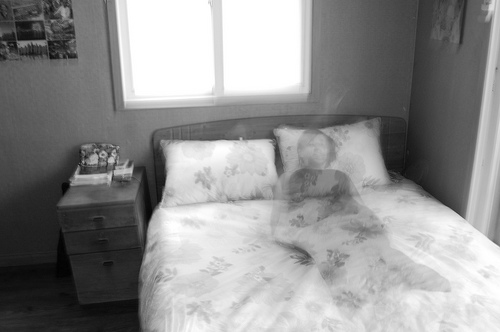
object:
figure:
[266, 129, 452, 316]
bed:
[131, 119, 499, 332]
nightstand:
[54, 165, 146, 308]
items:
[113, 159, 132, 181]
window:
[105, 1, 320, 103]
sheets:
[131, 174, 500, 331]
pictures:
[0, 0, 76, 63]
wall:
[4, 4, 404, 265]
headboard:
[154, 116, 404, 184]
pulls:
[91, 214, 105, 223]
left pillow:
[158, 137, 280, 208]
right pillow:
[274, 114, 391, 201]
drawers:
[63, 225, 142, 256]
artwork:
[428, 1, 465, 44]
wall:
[410, 3, 483, 207]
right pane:
[224, 1, 309, 98]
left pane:
[120, 0, 215, 104]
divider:
[207, 0, 227, 99]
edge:
[131, 165, 145, 203]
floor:
[3, 283, 72, 330]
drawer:
[59, 205, 136, 234]